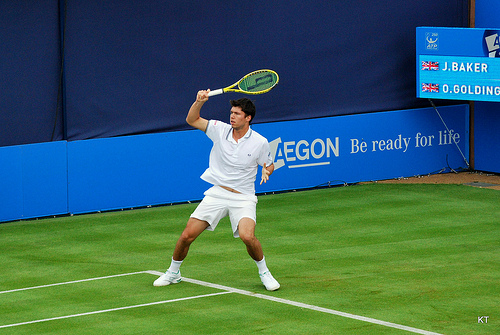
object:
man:
[148, 84, 284, 293]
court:
[1, 163, 499, 335]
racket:
[207, 65, 283, 96]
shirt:
[198, 115, 280, 203]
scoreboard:
[410, 18, 500, 105]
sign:
[261, 124, 461, 177]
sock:
[252, 253, 273, 276]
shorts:
[190, 185, 259, 240]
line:
[142, 264, 311, 335]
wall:
[0, 0, 500, 222]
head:
[223, 94, 262, 132]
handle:
[192, 79, 240, 108]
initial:
[242, 72, 277, 92]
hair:
[244, 101, 254, 111]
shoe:
[149, 265, 185, 288]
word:
[438, 58, 492, 75]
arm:
[182, 86, 219, 134]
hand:
[196, 87, 212, 103]